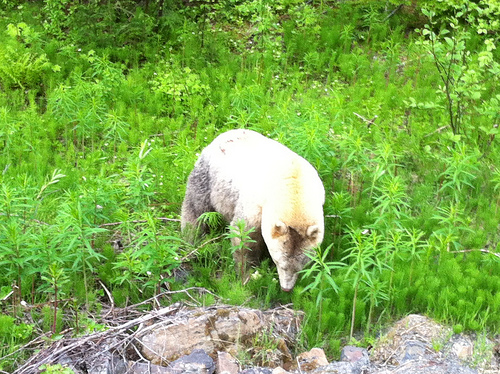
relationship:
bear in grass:
[179, 128, 329, 293] [0, 0, 499, 347]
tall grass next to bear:
[1, 52, 498, 339] [179, 128, 329, 293]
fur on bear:
[241, 150, 292, 192] [179, 128, 329, 293]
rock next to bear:
[77, 336, 144, 371] [179, 128, 329, 293]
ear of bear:
[302, 221, 319, 241] [179, 128, 329, 293]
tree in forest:
[420, 2, 499, 142] [5, 5, 495, 126]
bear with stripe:
[179, 128, 329, 293] [284, 155, 313, 232]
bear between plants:
[179, 128, 329, 293] [0, 10, 494, 369]